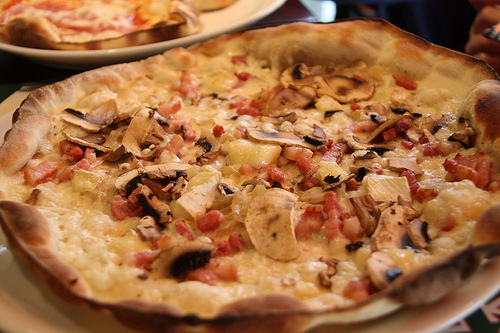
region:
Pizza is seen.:
[58, 27, 499, 331]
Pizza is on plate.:
[126, 131, 498, 331]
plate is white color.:
[411, 300, 491, 327]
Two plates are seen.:
[2, 28, 197, 110]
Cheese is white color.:
[75, 215, 126, 257]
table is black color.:
[295, 2, 385, 14]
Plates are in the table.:
[256, 2, 391, 43]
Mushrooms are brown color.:
[120, 110, 175, 197]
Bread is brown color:
[6, 207, 38, 249]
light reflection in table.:
[294, 5, 354, 20]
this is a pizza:
[18, 67, 442, 320]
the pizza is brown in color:
[345, 29, 390, 53]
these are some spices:
[118, 109, 349, 241]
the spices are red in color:
[198, 212, 233, 244]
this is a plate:
[32, 52, 96, 62]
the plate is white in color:
[207, 13, 238, 25]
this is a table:
[293, 6, 325, 20]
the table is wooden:
[286, 5, 323, 19]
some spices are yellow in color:
[236, 177, 283, 277]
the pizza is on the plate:
[7, 87, 227, 326]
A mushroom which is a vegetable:
[246, 126, 296, 149]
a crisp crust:
[21, 79, 79, 104]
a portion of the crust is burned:
[405, 271, 473, 299]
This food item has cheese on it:
[67, 216, 123, 255]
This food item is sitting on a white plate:
[11, 279, 59, 321]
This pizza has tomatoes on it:
[21, 162, 63, 182]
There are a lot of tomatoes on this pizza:
[298, 193, 353, 243]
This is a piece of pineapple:
[222, 137, 285, 174]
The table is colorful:
[473, 316, 499, 330]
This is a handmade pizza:
[20, 59, 456, 304]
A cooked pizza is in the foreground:
[12, 11, 489, 331]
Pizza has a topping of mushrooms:
[73, 51, 472, 299]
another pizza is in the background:
[5, 3, 230, 59]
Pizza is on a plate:
[8, 82, 498, 330]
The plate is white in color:
[7, 95, 499, 322]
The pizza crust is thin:
[16, 127, 294, 330]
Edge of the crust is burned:
[32, 273, 287, 332]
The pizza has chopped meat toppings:
[133, 92, 439, 262]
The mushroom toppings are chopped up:
[75, 92, 466, 272]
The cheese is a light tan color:
[117, 87, 467, 234]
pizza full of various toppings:
[1, 15, 498, 327]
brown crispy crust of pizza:
[0, 19, 499, 328]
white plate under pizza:
[0, 85, 499, 331]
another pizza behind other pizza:
[0, 0, 235, 49]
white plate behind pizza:
[1, 0, 286, 65]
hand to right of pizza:
[463, 3, 498, 67]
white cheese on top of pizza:
[31, 50, 492, 292]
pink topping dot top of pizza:
[25, 53, 489, 298]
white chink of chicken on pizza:
[365, 173, 410, 205]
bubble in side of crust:
[466, 75, 499, 151]